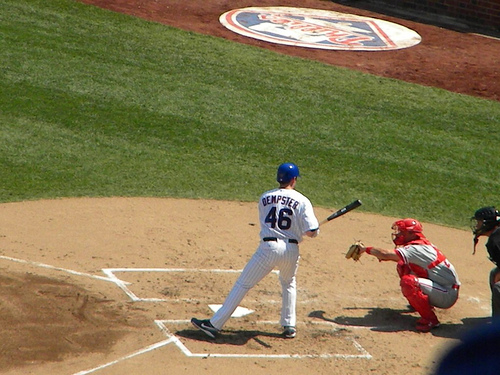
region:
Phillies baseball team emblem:
[217, 3, 424, 53]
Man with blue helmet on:
[185, 160, 321, 341]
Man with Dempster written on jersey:
[189, 158, 363, 337]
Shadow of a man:
[171, 324, 290, 347]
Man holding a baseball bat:
[188, 161, 361, 337]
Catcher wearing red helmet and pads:
[344, 217, 460, 332]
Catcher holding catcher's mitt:
[343, 215, 460, 331]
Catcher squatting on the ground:
[342, 215, 464, 332]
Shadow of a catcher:
[307, 301, 427, 335]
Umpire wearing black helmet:
[470, 200, 498, 332]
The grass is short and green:
[58, 42, 318, 159]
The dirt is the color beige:
[34, 200, 231, 261]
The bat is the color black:
[314, 192, 364, 251]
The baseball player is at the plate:
[191, 154, 366, 341]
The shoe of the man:
[186, 309, 222, 342]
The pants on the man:
[208, 240, 304, 331]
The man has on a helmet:
[271, 157, 304, 190]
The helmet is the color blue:
[271, 153, 303, 193]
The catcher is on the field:
[346, 217, 463, 339]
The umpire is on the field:
[458, 185, 498, 348]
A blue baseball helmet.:
[273, 160, 300, 181]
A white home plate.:
[201, 300, 251, 315]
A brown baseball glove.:
[345, 240, 360, 260]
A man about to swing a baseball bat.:
[187, 157, 362, 337]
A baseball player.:
[189, 163, 319, 338]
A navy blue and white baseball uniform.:
[209, 190, 318, 330]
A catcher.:
[342, 207, 460, 335]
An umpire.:
[469, 194, 499, 321]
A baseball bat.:
[310, 200, 361, 228]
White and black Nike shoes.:
[187, 318, 297, 339]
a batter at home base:
[187, 163, 362, 334]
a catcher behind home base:
[345, 215, 457, 328]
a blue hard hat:
[271, 161, 307, 183]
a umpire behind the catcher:
[470, 204, 495, 347]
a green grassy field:
[57, 84, 314, 179]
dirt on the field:
[45, 199, 212, 335]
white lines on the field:
[164, 308, 194, 358]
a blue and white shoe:
[189, 314, 216, 341]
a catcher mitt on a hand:
[347, 239, 363, 261]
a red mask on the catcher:
[390, 219, 423, 245]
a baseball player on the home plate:
[191, 164, 361, 340]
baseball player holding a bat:
[306, 191, 363, 238]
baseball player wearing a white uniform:
[210, 184, 317, 320]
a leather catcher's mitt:
[346, 239, 367, 262]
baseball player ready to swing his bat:
[192, 162, 363, 337]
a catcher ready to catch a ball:
[348, 217, 462, 334]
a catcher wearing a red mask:
[388, 220, 423, 246]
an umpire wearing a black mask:
[468, 207, 498, 239]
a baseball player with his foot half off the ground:
[190, 310, 219, 341]